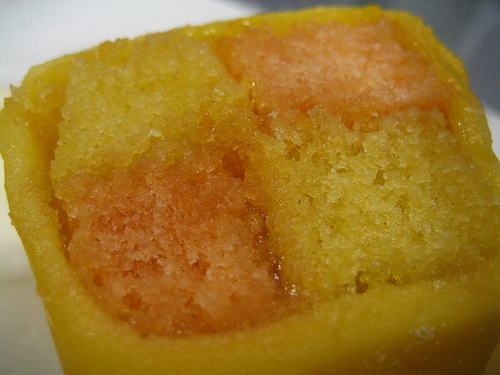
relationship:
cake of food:
[46, 40, 257, 213] [3, 2, 498, 372]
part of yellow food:
[280, 181, 416, 307] [0, 6, 500, 373]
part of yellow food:
[238, 105, 500, 306] [248, 109, 485, 279]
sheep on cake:
[41, 29, 500, 323] [1, 2, 498, 372]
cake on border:
[1, 0, 500, 375] [5, 129, 147, 351]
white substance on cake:
[409, 314, 440, 357] [17, 29, 486, 373]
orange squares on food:
[71, 10, 455, 336] [3, 2, 498, 372]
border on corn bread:
[1, 129, 149, 375] [21, 10, 496, 350]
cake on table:
[1, 0, 500, 375] [1, 0, 498, 374]